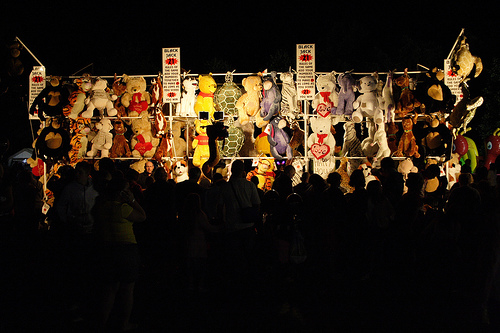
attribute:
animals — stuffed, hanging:
[38, 79, 157, 117]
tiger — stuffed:
[66, 76, 91, 115]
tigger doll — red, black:
[66, 75, 93, 124]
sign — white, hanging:
[294, 42, 317, 100]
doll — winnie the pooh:
[187, 73, 222, 131]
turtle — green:
[216, 122, 244, 153]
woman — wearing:
[97, 155, 149, 312]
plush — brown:
[87, 119, 111, 161]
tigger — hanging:
[62, 75, 89, 123]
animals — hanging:
[18, 53, 482, 204]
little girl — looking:
[173, 188, 221, 294]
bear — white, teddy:
[303, 111, 333, 163]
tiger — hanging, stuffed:
[64, 72, 91, 123]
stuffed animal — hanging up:
[191, 71, 216, 121]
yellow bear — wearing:
[191, 120, 213, 168]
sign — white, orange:
[291, 39, 319, 104]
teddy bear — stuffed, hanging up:
[192, 73, 227, 127]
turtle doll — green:
[215, 71, 247, 116]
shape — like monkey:
[29, 74, 62, 110]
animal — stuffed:
[28, 71, 69, 124]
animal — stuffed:
[217, 74, 240, 125]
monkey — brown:
[26, 75, 70, 115]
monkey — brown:
[24, 113, 67, 183]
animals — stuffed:
[47, 83, 349, 169]